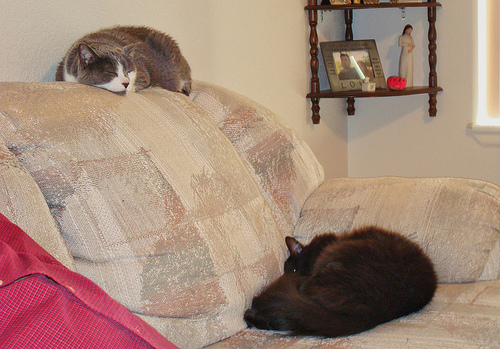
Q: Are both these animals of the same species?
A: Yes, all the animals are cats.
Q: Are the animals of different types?
A: No, all the animals are cats.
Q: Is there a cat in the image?
A: Yes, there is a cat.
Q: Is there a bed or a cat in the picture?
A: Yes, there is a cat.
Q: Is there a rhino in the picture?
A: No, there are no rhinos.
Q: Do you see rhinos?
A: No, there are no rhinos.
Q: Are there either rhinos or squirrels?
A: No, there are no rhinos or squirrels.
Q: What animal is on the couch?
A: The cat is on the couch.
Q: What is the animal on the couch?
A: The animal is a cat.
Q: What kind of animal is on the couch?
A: The animal is a cat.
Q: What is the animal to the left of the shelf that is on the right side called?
A: The animal is a cat.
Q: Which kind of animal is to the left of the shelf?
A: The animal is a cat.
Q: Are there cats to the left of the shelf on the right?
A: Yes, there is a cat to the left of the shelf.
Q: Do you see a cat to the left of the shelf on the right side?
A: Yes, there is a cat to the left of the shelf.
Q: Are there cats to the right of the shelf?
A: No, the cat is to the left of the shelf.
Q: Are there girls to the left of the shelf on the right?
A: No, there is a cat to the left of the shelf.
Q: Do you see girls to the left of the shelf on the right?
A: No, there is a cat to the left of the shelf.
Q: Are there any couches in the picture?
A: Yes, there is a couch.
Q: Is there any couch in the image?
A: Yes, there is a couch.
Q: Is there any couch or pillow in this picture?
A: Yes, there is a couch.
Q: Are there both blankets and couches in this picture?
A: Yes, there are both a couch and a blanket.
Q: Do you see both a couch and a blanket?
A: Yes, there are both a couch and a blanket.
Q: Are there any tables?
A: No, there are no tables.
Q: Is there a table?
A: No, there are no tables.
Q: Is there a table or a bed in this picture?
A: No, there are no tables or beds.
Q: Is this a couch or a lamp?
A: This is a couch.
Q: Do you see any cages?
A: No, there are no cages.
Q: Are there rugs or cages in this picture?
A: No, there are no cages or rugs.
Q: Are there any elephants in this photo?
A: No, there are no elephants.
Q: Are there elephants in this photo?
A: No, there are no elephants.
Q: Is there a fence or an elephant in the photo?
A: No, there are no elephants or fences.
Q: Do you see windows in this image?
A: Yes, there is a window.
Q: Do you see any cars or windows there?
A: Yes, there is a window.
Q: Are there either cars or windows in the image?
A: Yes, there is a window.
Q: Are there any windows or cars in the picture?
A: Yes, there is a window.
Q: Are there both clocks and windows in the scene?
A: No, there is a window but no clocks.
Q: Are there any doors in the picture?
A: No, there are no doors.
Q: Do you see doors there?
A: No, there are no doors.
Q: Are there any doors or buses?
A: No, there are no doors or buses.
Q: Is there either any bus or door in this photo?
A: No, there are no doors or buses.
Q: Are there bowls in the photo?
A: No, there are no bowls.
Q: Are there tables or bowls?
A: No, there are no bowls or tables.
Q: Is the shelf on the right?
A: Yes, the shelf is on the right of the image.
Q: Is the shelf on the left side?
A: No, the shelf is on the right of the image.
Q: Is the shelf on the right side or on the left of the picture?
A: The shelf is on the right of the image.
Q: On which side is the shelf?
A: The shelf is on the right of the image.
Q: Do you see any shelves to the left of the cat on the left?
A: No, the shelf is to the right of the cat.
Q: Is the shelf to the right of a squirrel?
A: No, the shelf is to the right of the cat.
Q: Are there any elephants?
A: No, there are no elephants.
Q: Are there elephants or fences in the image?
A: No, there are no elephants or fences.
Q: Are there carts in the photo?
A: No, there are no carts.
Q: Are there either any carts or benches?
A: No, there are no carts or benches.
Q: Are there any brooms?
A: No, there are no brooms.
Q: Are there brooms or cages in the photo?
A: No, there are no brooms or cages.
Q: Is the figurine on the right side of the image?
A: Yes, the figurine is on the right of the image.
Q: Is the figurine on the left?
A: No, the figurine is on the right of the image.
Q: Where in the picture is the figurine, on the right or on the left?
A: The figurine is on the right of the image.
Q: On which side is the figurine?
A: The figurine is on the right of the image.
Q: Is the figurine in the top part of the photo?
A: Yes, the figurine is in the top of the image.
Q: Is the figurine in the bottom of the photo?
A: No, the figurine is in the top of the image.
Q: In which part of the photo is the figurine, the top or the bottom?
A: The figurine is in the top of the image.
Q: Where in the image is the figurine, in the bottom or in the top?
A: The figurine is in the top of the image.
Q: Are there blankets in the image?
A: Yes, there is a blanket.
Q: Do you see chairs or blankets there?
A: Yes, there is a blanket.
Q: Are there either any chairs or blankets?
A: Yes, there is a blanket.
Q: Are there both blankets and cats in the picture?
A: Yes, there are both a blanket and a cat.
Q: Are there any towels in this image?
A: No, there are no towels.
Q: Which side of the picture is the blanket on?
A: The blanket is on the left of the image.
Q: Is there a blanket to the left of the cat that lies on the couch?
A: Yes, there is a blanket to the left of the cat.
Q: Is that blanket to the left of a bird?
A: No, the blanket is to the left of the cat.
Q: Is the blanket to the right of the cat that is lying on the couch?
A: No, the blanket is to the left of the cat.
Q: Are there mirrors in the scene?
A: No, there are no mirrors.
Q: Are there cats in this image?
A: Yes, there is a cat.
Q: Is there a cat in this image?
A: Yes, there is a cat.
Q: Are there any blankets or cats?
A: Yes, there is a cat.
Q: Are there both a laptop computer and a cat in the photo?
A: No, there is a cat but no laptops.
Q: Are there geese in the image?
A: No, there are no geese.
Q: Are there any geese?
A: No, there are no geese.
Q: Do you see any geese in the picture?
A: No, there are no geese.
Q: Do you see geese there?
A: No, there are no geese.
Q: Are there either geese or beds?
A: No, there are no geese or beds.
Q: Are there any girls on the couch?
A: No, there is a cat on the couch.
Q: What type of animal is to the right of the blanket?
A: The animal is a cat.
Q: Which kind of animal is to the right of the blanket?
A: The animal is a cat.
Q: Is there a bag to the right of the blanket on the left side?
A: No, there is a cat to the right of the blanket.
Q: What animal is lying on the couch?
A: The animal is a cat.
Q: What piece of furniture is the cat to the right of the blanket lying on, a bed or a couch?
A: The cat is lying on a couch.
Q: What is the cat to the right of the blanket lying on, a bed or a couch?
A: The cat is lying on a couch.